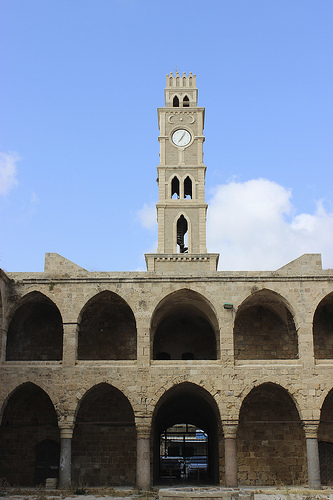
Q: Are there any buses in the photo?
A: No, there are no buses.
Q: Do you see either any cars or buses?
A: No, there are no buses or cars.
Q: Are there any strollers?
A: No, there are no strollers.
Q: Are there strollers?
A: No, there are no strollers.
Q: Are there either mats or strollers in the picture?
A: No, there are no strollers or mats.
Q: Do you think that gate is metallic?
A: Yes, the gate is metallic.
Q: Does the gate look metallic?
A: Yes, the gate is metallic.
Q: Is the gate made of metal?
A: Yes, the gate is made of metal.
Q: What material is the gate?
A: The gate is made of metal.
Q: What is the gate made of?
A: The gate is made of metal.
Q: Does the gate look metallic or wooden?
A: The gate is metallic.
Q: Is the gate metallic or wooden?
A: The gate is metallic.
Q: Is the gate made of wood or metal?
A: The gate is made of metal.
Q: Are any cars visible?
A: No, there are no cars.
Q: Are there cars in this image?
A: No, there are no cars.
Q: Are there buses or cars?
A: No, there are no cars or buses.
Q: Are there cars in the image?
A: No, there are no cars.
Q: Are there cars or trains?
A: No, there are no cars or trains.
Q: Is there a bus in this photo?
A: No, there are no buses.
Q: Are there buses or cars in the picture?
A: No, there are no buses or cars.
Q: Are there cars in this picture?
A: No, there are no cars.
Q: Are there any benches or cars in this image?
A: No, there are no cars or benches.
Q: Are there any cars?
A: No, there are no cars.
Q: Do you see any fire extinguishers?
A: No, there are no fire extinguishers.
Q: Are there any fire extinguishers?
A: No, there are no fire extinguishers.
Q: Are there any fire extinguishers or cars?
A: No, there are no fire extinguishers or cars.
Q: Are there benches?
A: No, there are no benches.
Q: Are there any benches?
A: No, there are no benches.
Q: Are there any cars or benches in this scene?
A: No, there are no benches or cars.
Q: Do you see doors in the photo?
A: Yes, there is a door.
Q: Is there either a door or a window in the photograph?
A: Yes, there is a door.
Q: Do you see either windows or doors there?
A: Yes, there is a door.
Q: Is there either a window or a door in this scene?
A: Yes, there is a door.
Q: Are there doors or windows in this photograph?
A: Yes, there is a door.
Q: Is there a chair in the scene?
A: No, there are no chairs.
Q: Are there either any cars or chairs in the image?
A: No, there are no chairs or cars.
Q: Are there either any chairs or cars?
A: No, there are no chairs or cars.